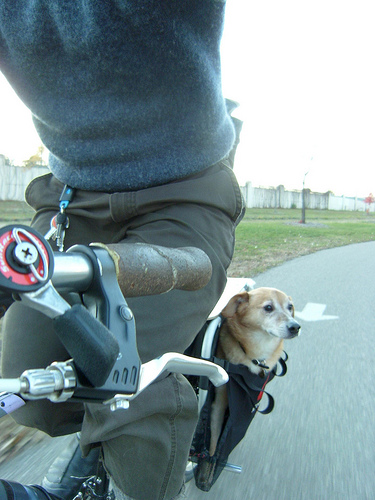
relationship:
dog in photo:
[220, 274, 295, 402] [28, 11, 371, 475]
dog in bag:
[220, 274, 295, 402] [189, 375, 276, 460]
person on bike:
[24, 31, 240, 307] [2, 230, 290, 496]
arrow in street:
[286, 281, 361, 345] [274, 241, 373, 463]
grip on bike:
[56, 296, 153, 397] [2, 230, 290, 496]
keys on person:
[19, 171, 81, 262] [24, 31, 240, 307]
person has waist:
[24, 31, 240, 307] [33, 157, 245, 200]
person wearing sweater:
[24, 31, 240, 307] [16, 10, 214, 162]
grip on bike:
[56, 296, 153, 397] [12, 239, 290, 421]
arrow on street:
[286, 281, 361, 345] [274, 241, 373, 463]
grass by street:
[246, 212, 370, 255] [274, 241, 373, 463]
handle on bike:
[41, 236, 239, 312] [12, 239, 290, 421]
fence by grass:
[244, 183, 348, 211] [246, 212, 370, 255]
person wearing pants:
[24, 31, 240, 307] [79, 180, 230, 366]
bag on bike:
[189, 375, 276, 460] [12, 239, 290, 421]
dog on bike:
[220, 274, 295, 402] [12, 239, 290, 421]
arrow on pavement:
[286, 281, 361, 345] [274, 241, 373, 463]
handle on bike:
[41, 236, 239, 312] [2, 230, 290, 496]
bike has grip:
[2, 230, 290, 496] [56, 296, 153, 397]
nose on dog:
[281, 318, 310, 339] [220, 274, 295, 402]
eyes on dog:
[256, 296, 298, 316] [220, 274, 295, 402]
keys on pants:
[19, 171, 81, 262] [79, 180, 230, 366]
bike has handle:
[12, 239, 290, 421] [41, 236, 239, 312]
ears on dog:
[212, 294, 259, 334] [220, 274, 295, 402]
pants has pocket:
[79, 180, 230, 366] [174, 170, 252, 237]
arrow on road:
[286, 281, 361, 345] [274, 241, 373, 463]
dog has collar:
[220, 274, 295, 402] [226, 344, 275, 371]